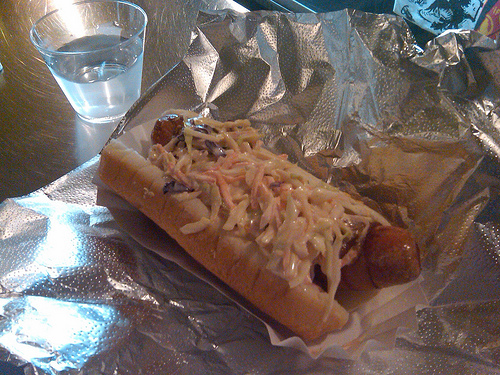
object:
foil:
[1, 8, 498, 374]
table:
[1, 1, 241, 203]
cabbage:
[150, 116, 371, 305]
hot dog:
[152, 114, 420, 289]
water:
[49, 35, 146, 123]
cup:
[30, 1, 148, 122]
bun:
[100, 107, 419, 340]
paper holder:
[92, 107, 430, 359]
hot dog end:
[339, 225, 424, 288]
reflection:
[1, 192, 119, 373]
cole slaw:
[151, 115, 372, 323]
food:
[95, 108, 423, 341]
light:
[49, 1, 85, 38]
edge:
[197, 9, 498, 96]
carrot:
[202, 169, 234, 208]